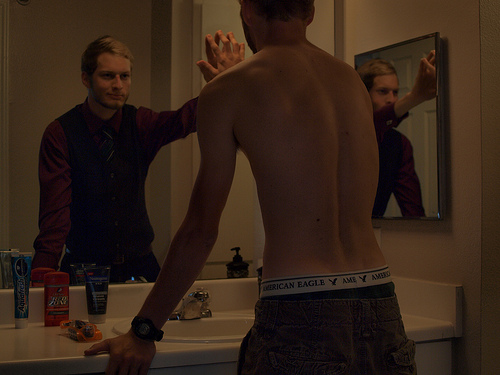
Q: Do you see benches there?
A: No, there are no benches.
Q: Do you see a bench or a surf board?
A: No, there are no benches or surfboards.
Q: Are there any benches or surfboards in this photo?
A: No, there are no benches or surfboards.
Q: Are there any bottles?
A: Yes, there is a bottle.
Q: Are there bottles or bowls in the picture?
A: Yes, there is a bottle.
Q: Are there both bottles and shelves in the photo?
A: No, there is a bottle but no shelves.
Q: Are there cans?
A: No, there are no cans.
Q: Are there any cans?
A: No, there are no cans.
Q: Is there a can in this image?
A: No, there are no cans.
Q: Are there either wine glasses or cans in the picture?
A: No, there are no cans or wine glasses.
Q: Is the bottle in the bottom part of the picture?
A: Yes, the bottle is in the bottom of the image.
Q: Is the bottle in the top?
A: No, the bottle is in the bottom of the image.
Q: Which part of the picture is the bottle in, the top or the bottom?
A: The bottle is in the bottom of the image.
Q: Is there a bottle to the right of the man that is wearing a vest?
A: Yes, there is a bottle to the right of the man.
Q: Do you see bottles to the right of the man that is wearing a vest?
A: Yes, there is a bottle to the right of the man.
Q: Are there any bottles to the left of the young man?
A: No, the bottle is to the right of the man.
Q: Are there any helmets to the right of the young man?
A: No, there is a bottle to the right of the man.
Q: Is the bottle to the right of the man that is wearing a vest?
A: Yes, the bottle is to the right of the man.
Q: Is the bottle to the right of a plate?
A: No, the bottle is to the right of the man.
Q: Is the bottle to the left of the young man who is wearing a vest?
A: No, the bottle is to the right of the man.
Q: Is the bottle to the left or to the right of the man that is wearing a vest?
A: The bottle is to the right of the man.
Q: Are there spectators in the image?
A: No, there are no spectators.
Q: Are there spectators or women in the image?
A: No, there are no spectators or women.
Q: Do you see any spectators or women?
A: No, there are no spectators or women.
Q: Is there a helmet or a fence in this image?
A: No, there are no helmets or fences.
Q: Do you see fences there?
A: No, there are no fences.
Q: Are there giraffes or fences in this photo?
A: No, there are no fences or giraffes.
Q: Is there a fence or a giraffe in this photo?
A: No, there are no fences or giraffes.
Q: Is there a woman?
A: No, there are no women.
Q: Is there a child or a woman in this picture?
A: No, there are no women or children.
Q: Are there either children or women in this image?
A: No, there are no women or children.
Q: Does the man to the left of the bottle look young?
A: Yes, the man is young.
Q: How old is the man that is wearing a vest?
A: The man is young.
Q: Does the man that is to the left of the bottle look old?
A: No, the man is young.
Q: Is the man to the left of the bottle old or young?
A: The man is young.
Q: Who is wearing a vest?
A: The man is wearing a vest.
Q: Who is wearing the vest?
A: The man is wearing a vest.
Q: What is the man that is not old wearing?
A: The man is wearing a vest.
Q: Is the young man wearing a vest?
A: Yes, the man is wearing a vest.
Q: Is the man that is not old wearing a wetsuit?
A: No, the man is wearing a vest.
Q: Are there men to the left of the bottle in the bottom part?
A: Yes, there is a man to the left of the bottle.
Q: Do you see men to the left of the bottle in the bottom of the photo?
A: Yes, there is a man to the left of the bottle.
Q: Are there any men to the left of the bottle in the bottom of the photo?
A: Yes, there is a man to the left of the bottle.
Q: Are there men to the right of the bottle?
A: No, the man is to the left of the bottle.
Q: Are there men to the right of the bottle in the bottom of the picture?
A: No, the man is to the left of the bottle.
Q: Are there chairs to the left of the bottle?
A: No, there is a man to the left of the bottle.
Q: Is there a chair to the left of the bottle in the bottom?
A: No, there is a man to the left of the bottle.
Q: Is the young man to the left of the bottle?
A: Yes, the man is to the left of the bottle.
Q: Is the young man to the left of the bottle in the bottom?
A: Yes, the man is to the left of the bottle.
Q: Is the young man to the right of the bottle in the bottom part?
A: No, the man is to the left of the bottle.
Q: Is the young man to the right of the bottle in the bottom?
A: No, the man is to the left of the bottle.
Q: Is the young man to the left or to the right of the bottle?
A: The man is to the left of the bottle.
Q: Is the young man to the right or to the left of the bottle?
A: The man is to the left of the bottle.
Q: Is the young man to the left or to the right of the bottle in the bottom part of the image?
A: The man is to the left of the bottle.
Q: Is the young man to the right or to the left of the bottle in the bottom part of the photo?
A: The man is to the left of the bottle.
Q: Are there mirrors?
A: Yes, there is a mirror.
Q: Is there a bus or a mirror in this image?
A: Yes, there is a mirror.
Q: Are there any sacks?
A: No, there are no sacks.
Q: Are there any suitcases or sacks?
A: No, there are no sacks or suitcases.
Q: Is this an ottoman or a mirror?
A: This is a mirror.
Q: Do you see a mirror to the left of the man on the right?
A: Yes, there is a mirror to the left of the man.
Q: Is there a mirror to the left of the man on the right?
A: Yes, there is a mirror to the left of the man.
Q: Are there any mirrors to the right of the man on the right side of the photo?
A: No, the mirror is to the left of the man.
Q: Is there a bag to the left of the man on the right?
A: No, there is a mirror to the left of the man.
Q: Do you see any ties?
A: Yes, there is a tie.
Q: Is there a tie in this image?
A: Yes, there is a tie.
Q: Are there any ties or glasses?
A: Yes, there is a tie.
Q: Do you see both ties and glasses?
A: No, there is a tie but no glasses.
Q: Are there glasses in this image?
A: No, there are no glasses.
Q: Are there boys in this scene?
A: No, there are no boys.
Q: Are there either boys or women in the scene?
A: No, there are no boys or women.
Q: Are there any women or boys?
A: No, there are no boys or women.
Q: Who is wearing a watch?
A: The man is wearing a watch.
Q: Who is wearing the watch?
A: The man is wearing a watch.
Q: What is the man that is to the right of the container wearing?
A: The man is wearing a watch.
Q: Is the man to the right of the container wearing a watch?
A: Yes, the man is wearing a watch.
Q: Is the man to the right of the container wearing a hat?
A: No, the man is wearing a watch.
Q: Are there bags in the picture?
A: No, there are no bags.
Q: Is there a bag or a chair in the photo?
A: No, there are no bags or chairs.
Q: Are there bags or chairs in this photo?
A: No, there are no bags or chairs.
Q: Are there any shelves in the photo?
A: No, there are no shelves.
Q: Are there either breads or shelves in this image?
A: No, there are no shelves or breads.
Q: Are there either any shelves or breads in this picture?
A: No, there are no shelves or breads.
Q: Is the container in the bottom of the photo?
A: Yes, the container is in the bottom of the image.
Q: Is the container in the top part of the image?
A: No, the container is in the bottom of the image.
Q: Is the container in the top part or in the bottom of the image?
A: The container is in the bottom of the image.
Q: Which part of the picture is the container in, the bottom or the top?
A: The container is in the bottom of the image.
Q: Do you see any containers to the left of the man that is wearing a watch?
A: Yes, there is a container to the left of the man.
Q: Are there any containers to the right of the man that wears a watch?
A: No, the container is to the left of the man.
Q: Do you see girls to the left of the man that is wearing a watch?
A: No, there is a container to the left of the man.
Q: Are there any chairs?
A: No, there are no chairs.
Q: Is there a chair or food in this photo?
A: No, there are no chairs or food.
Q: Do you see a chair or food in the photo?
A: No, there are no chairs or food.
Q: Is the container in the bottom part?
A: Yes, the container is in the bottom of the image.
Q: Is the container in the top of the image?
A: No, the container is in the bottom of the image.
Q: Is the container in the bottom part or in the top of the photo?
A: The container is in the bottom of the image.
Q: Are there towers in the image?
A: No, there are no towers.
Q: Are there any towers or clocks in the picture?
A: No, there are no towers or clocks.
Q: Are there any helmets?
A: No, there are no helmets.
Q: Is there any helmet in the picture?
A: No, there are no helmets.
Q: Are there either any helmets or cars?
A: No, there are no helmets or cars.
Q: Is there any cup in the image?
A: No, there are no cups.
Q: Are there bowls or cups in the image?
A: No, there are no cups or bowls.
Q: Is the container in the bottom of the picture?
A: Yes, the container is in the bottom of the image.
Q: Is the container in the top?
A: No, the container is in the bottom of the image.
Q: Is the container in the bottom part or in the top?
A: The container is in the bottom of the image.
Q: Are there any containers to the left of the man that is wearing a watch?
A: Yes, there is a container to the left of the man.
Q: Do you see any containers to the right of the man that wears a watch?
A: No, the container is to the left of the man.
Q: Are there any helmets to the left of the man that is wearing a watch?
A: No, there is a container to the left of the man.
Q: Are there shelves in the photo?
A: No, there are no shelves.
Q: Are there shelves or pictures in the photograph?
A: No, there are no shelves or pictures.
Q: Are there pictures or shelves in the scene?
A: No, there are no shelves or pictures.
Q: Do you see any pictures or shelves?
A: No, there are no shelves or pictures.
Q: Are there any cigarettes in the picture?
A: No, there are no cigarettes.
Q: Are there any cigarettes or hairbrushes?
A: No, there are no cigarettes or hairbrushes.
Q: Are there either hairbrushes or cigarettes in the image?
A: No, there are no cigarettes or hairbrushes.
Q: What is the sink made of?
A: The sink is made of porcelain.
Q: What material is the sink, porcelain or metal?
A: The sink is made of porcelain.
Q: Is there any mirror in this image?
A: Yes, there is a mirror.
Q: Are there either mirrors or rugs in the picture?
A: Yes, there is a mirror.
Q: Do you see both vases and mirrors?
A: No, there is a mirror but no vases.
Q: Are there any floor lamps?
A: No, there are no floor lamps.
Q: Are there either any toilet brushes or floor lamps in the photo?
A: No, there are no floor lamps or toilet brushes.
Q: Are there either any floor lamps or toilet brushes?
A: No, there are no floor lamps or toilet brushes.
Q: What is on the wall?
A: The mirror is on the wall.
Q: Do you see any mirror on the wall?
A: Yes, there is a mirror on the wall.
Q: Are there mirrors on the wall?
A: Yes, there is a mirror on the wall.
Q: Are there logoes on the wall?
A: No, there is a mirror on the wall.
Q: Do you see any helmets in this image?
A: No, there are no helmets.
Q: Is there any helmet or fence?
A: No, there are no helmets or fences.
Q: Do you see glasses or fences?
A: No, there are no glasses or fences.